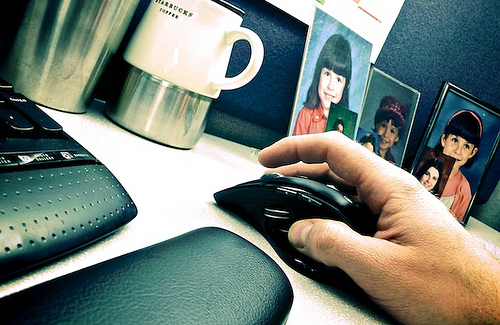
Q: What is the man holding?
A: A mouse.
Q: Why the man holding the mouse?
A: He's using it.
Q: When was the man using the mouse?
A: Now.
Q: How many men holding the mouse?
A: One.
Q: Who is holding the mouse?
A: A man.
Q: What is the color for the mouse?
A: Black.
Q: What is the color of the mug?
A: White.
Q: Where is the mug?
A: On the table.